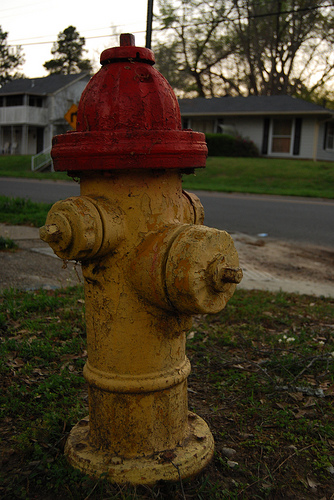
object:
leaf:
[276, 397, 297, 412]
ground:
[1, 193, 334, 498]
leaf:
[11, 355, 28, 376]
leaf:
[232, 360, 245, 371]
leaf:
[315, 333, 333, 348]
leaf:
[304, 474, 321, 490]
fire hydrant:
[37, 30, 243, 490]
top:
[49, 27, 208, 177]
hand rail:
[28, 131, 59, 176]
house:
[167, 88, 333, 173]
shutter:
[259, 112, 274, 159]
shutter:
[290, 115, 305, 157]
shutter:
[180, 113, 193, 133]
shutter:
[212, 115, 223, 137]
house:
[0, 66, 100, 174]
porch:
[0, 93, 47, 127]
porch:
[0, 122, 46, 161]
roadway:
[0, 168, 334, 259]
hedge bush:
[202, 131, 260, 160]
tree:
[40, 23, 96, 82]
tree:
[148, 0, 247, 99]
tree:
[0, 22, 29, 85]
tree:
[224, 0, 334, 109]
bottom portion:
[38, 172, 243, 482]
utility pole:
[143, 0, 156, 52]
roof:
[176, 94, 333, 120]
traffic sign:
[63, 101, 82, 131]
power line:
[0, 0, 333, 53]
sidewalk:
[1, 221, 334, 308]